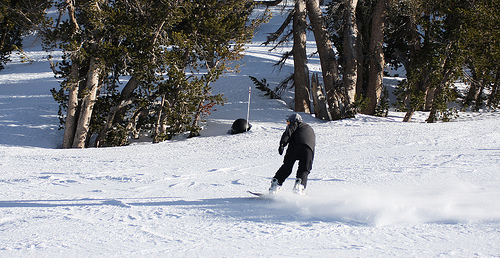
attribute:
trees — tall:
[166, 8, 498, 125]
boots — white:
[266, 174, 311, 199]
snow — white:
[375, 126, 435, 175]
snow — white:
[1, 1, 497, 255]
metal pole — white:
[244, 85, 254, 130]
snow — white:
[2, 142, 495, 252]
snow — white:
[140, 154, 207, 211]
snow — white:
[122, 150, 190, 199]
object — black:
[220, 117, 254, 136]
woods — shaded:
[28, 0, 221, 150]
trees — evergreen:
[172, 15, 254, 114]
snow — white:
[16, 136, 480, 256]